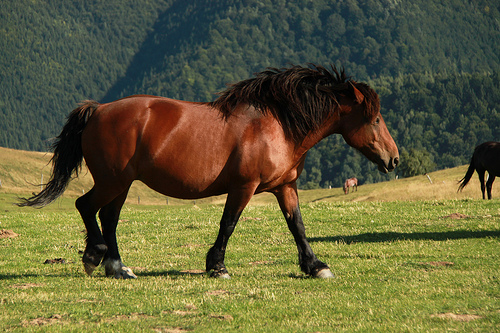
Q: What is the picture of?
A: A horse.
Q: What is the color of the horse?
A: Brown.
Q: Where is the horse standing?
A: On a grass ground.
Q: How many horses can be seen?
A: Three.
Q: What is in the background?
A: Hills thickly covered by trees.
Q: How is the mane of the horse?
A: It is thick and long and dark-colored.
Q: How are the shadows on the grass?
A: Long shadows.